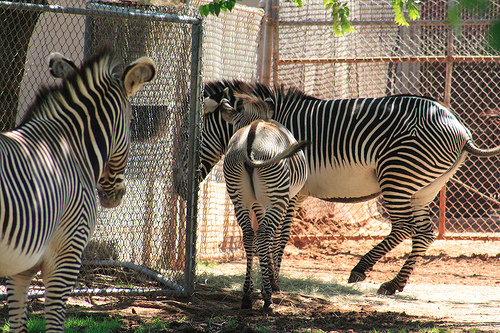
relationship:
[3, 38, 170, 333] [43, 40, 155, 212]
zebra has a head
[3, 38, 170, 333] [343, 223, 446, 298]
zebra has legs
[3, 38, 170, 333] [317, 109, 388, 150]
zebra has skin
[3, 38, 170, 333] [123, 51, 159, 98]
zebra has a ear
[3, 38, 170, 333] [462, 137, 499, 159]
zebra has a tail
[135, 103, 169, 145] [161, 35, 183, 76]
window on wall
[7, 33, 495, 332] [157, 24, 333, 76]
zebras in a enclosure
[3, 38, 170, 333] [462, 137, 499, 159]
zebra has a swinging tail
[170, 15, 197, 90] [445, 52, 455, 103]
chain link fence has a pole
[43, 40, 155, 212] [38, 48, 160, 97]
zebra head has ears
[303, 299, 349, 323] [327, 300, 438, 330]
ground has a shadow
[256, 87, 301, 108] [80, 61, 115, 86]
neck has a mane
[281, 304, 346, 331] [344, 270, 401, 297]
dirt under hooves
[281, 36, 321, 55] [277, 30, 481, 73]
sun reflection on fence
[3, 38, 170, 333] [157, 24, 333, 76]
zebra in an enclosure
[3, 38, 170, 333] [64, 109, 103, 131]
zebra has stripes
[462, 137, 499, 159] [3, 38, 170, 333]
tail of zebra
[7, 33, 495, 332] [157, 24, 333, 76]
zebras in an enclosure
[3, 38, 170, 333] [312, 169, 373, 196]
zebra has a belly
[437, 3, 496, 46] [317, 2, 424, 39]
tree has leaves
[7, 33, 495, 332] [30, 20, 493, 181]
zebras in a pen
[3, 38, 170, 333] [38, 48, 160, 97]
zebra has ears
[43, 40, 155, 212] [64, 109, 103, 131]
head has stripes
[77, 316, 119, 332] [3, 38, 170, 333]
grass under zebra